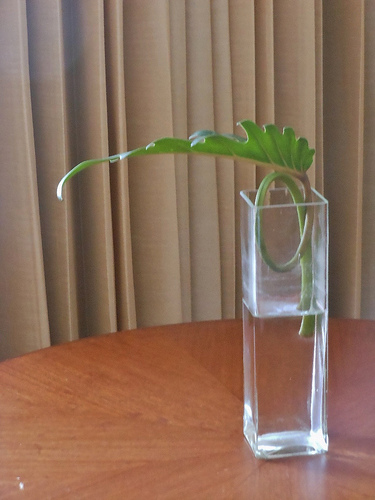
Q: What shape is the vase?
A: Square.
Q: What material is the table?
A: Wood.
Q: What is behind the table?
A: Curtain.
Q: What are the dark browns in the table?
A: Wood grains.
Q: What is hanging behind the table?
A: Curtain.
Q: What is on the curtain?
A: Pleats.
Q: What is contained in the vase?
A: Water.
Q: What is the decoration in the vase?
A: Leaf.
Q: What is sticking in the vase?
A: Stem.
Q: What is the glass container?
A: Vase.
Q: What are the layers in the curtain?
A: Creases.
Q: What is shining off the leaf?
A: Light.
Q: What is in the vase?
A: A plant.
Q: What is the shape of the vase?
A: Rectangle.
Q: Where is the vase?
A: On a table.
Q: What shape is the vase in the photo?
A: Square.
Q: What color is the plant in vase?
A: Green.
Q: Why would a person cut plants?
A: To display.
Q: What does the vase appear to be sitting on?
A: Table.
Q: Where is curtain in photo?
A: Background.